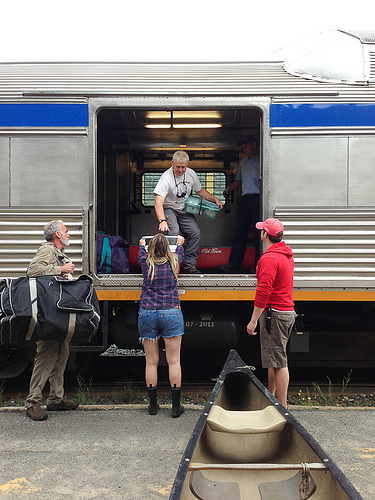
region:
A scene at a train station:
[6, 73, 360, 423]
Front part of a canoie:
[159, 351, 342, 492]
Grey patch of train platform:
[20, 433, 128, 488]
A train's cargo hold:
[17, 152, 355, 293]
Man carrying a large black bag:
[10, 214, 96, 415]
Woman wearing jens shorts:
[134, 226, 192, 418]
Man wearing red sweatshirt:
[248, 208, 297, 336]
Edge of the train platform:
[300, 376, 369, 418]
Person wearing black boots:
[134, 363, 189, 421]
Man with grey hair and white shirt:
[166, 149, 196, 197]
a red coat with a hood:
[252, 241, 294, 309]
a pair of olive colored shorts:
[258, 304, 294, 368]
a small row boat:
[176, 346, 361, 498]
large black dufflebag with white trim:
[2, 274, 99, 347]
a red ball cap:
[254, 218, 283, 235]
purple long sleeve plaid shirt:
[137, 246, 187, 306]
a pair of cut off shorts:
[137, 309, 183, 340]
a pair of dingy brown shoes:
[25, 396, 79, 420]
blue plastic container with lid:
[185, 193, 219, 217]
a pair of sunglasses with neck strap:
[171, 177, 187, 198]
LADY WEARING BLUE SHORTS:
[148, 317, 173, 327]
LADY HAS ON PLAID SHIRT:
[156, 274, 169, 291]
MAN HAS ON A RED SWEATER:
[277, 267, 287, 286]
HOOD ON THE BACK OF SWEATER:
[274, 243, 291, 255]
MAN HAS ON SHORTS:
[271, 347, 278, 354]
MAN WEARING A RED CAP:
[260, 215, 280, 231]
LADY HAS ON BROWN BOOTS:
[173, 384, 181, 409]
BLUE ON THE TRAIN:
[295, 106, 344, 125]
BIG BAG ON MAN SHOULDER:
[4, 273, 96, 337]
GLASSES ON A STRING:
[178, 191, 183, 199]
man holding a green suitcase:
[186, 195, 222, 220]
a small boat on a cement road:
[166, 349, 360, 497]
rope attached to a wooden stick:
[298, 464, 316, 499]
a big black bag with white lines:
[1, 277, 100, 345]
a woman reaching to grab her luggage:
[138, 234, 185, 416]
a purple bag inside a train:
[99, 230, 130, 273]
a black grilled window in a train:
[135, 169, 227, 210]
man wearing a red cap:
[256, 219, 283, 236]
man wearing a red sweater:
[254, 241, 293, 312]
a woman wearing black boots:
[147, 382, 183, 415]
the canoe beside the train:
[150, 341, 363, 496]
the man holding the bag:
[19, 218, 83, 415]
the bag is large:
[0, 269, 108, 350]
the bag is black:
[3, 271, 107, 352]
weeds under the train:
[76, 372, 105, 407]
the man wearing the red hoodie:
[253, 217, 314, 402]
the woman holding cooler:
[132, 234, 193, 418]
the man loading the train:
[148, 145, 217, 263]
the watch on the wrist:
[158, 216, 170, 226]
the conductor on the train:
[217, 130, 273, 276]